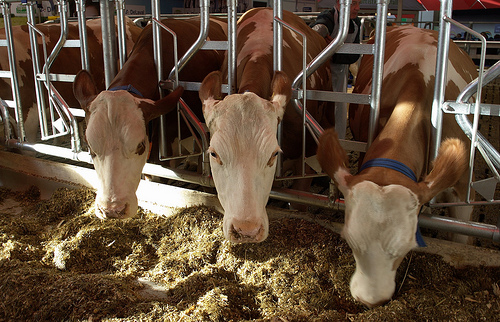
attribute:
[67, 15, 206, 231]
cow — brown, feeding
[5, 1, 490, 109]
fence — silver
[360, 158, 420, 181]
collar — blue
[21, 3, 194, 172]
gate — metal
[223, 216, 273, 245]
nose — pink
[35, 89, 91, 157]
light — bright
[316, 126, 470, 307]
cow — brown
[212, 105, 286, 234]
spot — white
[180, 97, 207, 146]
tie — multi-colored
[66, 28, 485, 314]
cows — fed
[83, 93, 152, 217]
head — white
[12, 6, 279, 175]
gates — metal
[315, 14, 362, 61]
shirt — black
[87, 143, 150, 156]
eyes — brown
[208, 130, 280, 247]
face — white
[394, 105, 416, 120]
patch — white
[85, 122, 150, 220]
face — white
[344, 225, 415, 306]
face — white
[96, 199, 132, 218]
nose — pink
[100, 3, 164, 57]
bars — metal